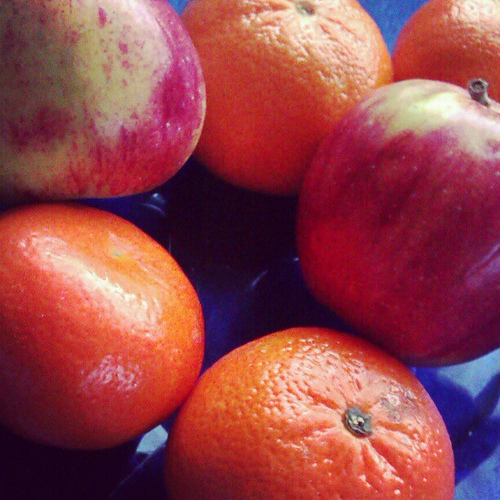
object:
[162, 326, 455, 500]
orange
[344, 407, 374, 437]
dimple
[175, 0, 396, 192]
orange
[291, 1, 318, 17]
dimple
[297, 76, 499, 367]
apple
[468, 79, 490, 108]
stem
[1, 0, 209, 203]
apple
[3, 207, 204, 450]
orange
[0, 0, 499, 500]
blue cloth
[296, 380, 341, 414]
mark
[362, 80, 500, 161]
patch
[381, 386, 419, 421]
bruise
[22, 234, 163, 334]
light